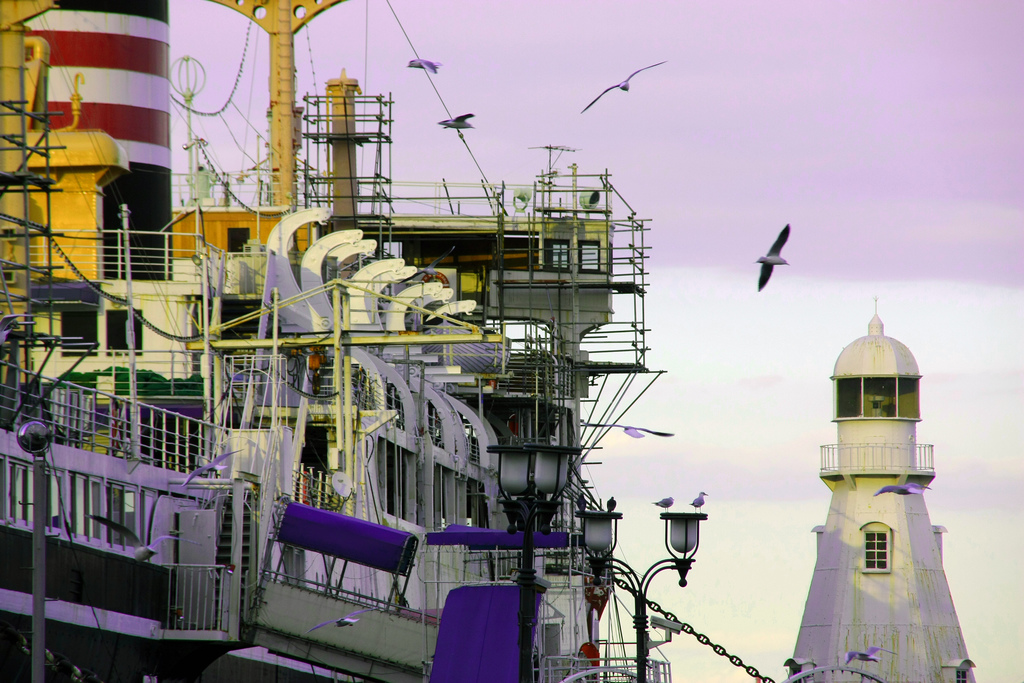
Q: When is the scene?
A: Daytime.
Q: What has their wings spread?
A: The birds.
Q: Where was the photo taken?
A: Near a lighthouse.